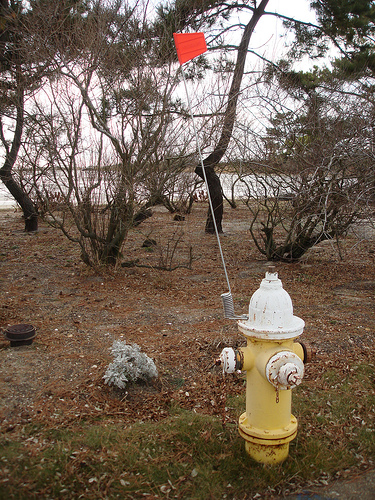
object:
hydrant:
[213, 265, 314, 466]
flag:
[172, 32, 237, 320]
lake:
[0, 173, 356, 202]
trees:
[1, 1, 116, 232]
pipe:
[4, 323, 36, 348]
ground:
[0, 193, 373, 500]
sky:
[239, 3, 375, 128]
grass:
[313, 385, 375, 471]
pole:
[180, 64, 238, 320]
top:
[236, 265, 306, 341]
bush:
[102, 338, 160, 391]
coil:
[220, 292, 234, 319]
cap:
[215, 347, 237, 374]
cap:
[265, 350, 305, 392]